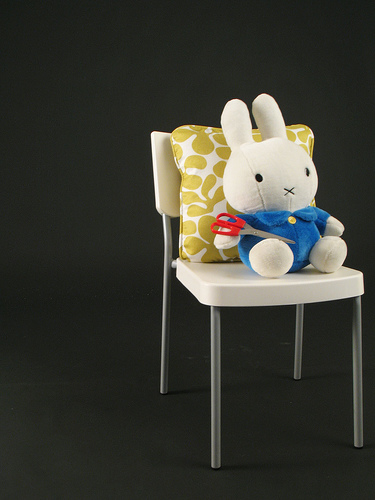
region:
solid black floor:
[15, 406, 148, 459]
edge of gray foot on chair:
[146, 387, 182, 403]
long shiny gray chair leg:
[206, 316, 237, 476]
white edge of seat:
[192, 274, 352, 324]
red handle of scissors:
[204, 209, 250, 234]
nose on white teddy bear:
[279, 180, 313, 205]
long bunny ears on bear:
[217, 84, 305, 145]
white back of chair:
[126, 123, 201, 214]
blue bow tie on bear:
[247, 200, 346, 234]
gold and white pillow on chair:
[156, 108, 325, 314]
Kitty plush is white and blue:
[195, 81, 349, 282]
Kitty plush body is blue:
[230, 202, 330, 257]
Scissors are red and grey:
[200, 206, 299, 249]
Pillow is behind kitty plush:
[157, 113, 330, 267]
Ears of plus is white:
[201, 85, 302, 148]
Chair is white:
[130, 116, 373, 471]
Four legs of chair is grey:
[150, 303, 368, 483]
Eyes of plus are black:
[245, 160, 315, 187]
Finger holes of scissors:
[203, 201, 250, 239]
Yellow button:
[281, 213, 298, 225]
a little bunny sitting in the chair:
[205, 94, 352, 269]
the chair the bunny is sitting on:
[139, 131, 358, 490]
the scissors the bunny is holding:
[215, 212, 291, 246]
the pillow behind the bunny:
[169, 125, 320, 263]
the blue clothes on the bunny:
[230, 207, 340, 272]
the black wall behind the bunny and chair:
[1, 1, 369, 493]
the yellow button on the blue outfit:
[284, 214, 294, 223]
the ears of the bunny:
[220, 98, 284, 143]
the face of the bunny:
[247, 155, 316, 210]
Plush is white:
[199, 82, 354, 281]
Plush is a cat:
[191, 77, 359, 289]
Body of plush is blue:
[196, 90, 361, 282]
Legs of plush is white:
[247, 230, 348, 273]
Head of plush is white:
[214, 138, 329, 212]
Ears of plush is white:
[214, 88, 294, 145]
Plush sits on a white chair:
[139, 89, 374, 474]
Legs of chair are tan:
[152, 307, 371, 484]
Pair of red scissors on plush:
[204, 204, 296, 249]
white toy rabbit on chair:
[209, 87, 356, 280]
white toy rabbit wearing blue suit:
[209, 88, 355, 284]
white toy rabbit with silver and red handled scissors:
[206, 85, 352, 276]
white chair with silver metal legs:
[145, 120, 370, 469]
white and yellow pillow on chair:
[170, 113, 317, 257]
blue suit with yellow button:
[225, 199, 337, 272]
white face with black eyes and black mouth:
[218, 135, 318, 221]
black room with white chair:
[1, 1, 369, 491]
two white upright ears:
[217, 91, 286, 151]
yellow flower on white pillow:
[184, 210, 244, 259]